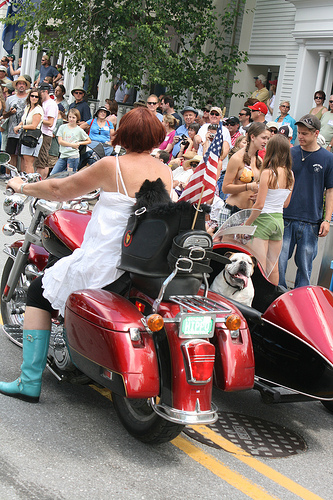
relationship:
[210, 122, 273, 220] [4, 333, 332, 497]
girl standing by street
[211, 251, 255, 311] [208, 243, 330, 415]
bulldog riding in sidecar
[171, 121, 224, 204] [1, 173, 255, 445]
flag on back of motorcycle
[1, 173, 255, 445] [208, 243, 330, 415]
motorcycle has sidecar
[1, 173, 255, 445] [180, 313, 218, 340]
motorcycle has license plate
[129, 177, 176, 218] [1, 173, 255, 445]
cat riding on motorcycle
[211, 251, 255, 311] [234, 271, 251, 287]
bulldog has tongue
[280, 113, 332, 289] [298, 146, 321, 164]
man has neck chain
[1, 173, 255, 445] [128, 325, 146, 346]
motorcycle has turn signal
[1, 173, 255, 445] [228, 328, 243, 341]
motorcycle has right turn signal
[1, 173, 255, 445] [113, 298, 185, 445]
motorcycle has tire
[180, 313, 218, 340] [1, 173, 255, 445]
license plate on back of motorcycle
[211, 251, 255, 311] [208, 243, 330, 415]
bulldog inside sidecar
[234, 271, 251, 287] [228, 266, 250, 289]
tongue hanging out of mouth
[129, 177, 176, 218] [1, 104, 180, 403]
cat in back of lady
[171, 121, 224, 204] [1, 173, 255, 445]
flag attached to motorcycle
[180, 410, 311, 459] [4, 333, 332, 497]
man hole cover on street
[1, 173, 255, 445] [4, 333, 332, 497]
motorcycle on street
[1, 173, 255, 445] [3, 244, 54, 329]
motorcycle has wheel